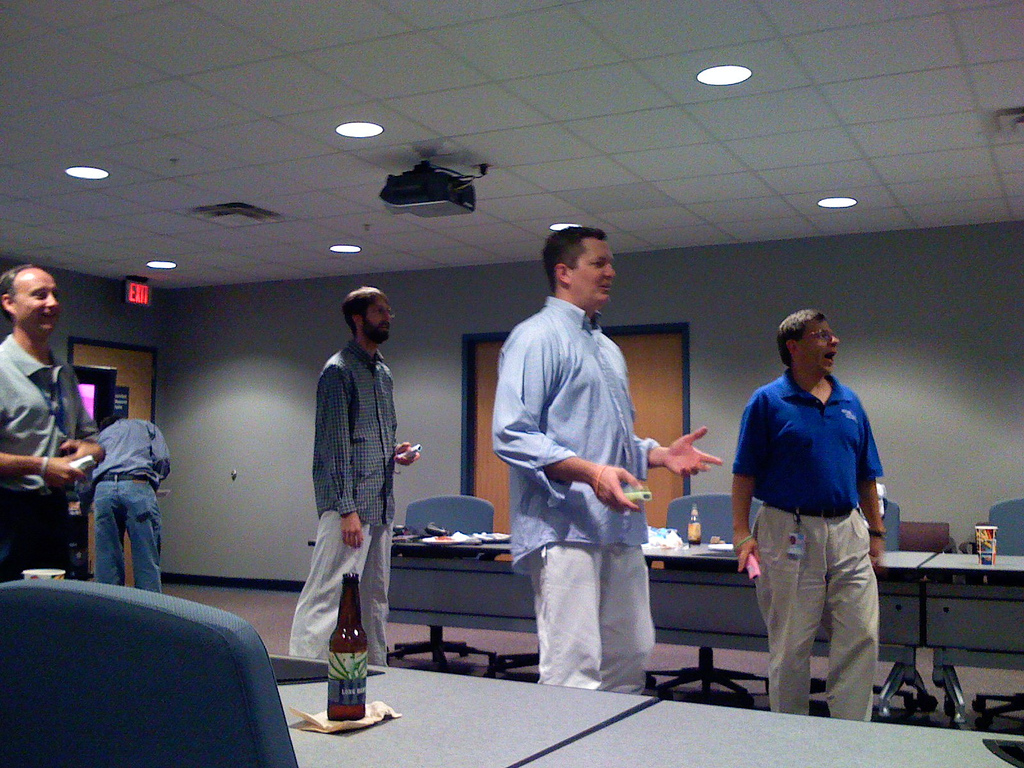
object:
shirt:
[733, 369, 886, 519]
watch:
[870, 528, 886, 537]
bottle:
[325, 572, 369, 721]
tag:
[788, 531, 805, 561]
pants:
[751, 508, 880, 721]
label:
[325, 651, 371, 707]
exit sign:
[128, 284, 150, 306]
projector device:
[380, 160, 479, 219]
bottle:
[329, 575, 365, 718]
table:
[265, 655, 1021, 766]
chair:
[0, 577, 299, 766]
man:
[74, 419, 170, 592]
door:
[68, 338, 158, 588]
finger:
[687, 425, 709, 442]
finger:
[696, 453, 723, 467]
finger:
[614, 468, 642, 490]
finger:
[611, 488, 639, 510]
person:
[287, 287, 426, 666]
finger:
[348, 529, 354, 548]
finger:
[677, 466, 686, 478]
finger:
[679, 464, 699, 476]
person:
[731, 308, 887, 720]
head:
[540, 227, 619, 309]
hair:
[544, 226, 609, 292]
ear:
[555, 263, 572, 284]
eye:
[588, 258, 615, 269]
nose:
[602, 263, 616, 278]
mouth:
[595, 281, 611, 292]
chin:
[573, 289, 612, 306]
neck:
[551, 289, 589, 317]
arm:
[488, 315, 597, 486]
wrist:
[555, 457, 598, 487]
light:
[696, 65, 754, 87]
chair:
[403, 494, 491, 531]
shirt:
[488, 297, 657, 578]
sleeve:
[731, 388, 770, 481]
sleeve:
[848, 389, 884, 484]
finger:
[737, 546, 751, 573]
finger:
[870, 551, 879, 570]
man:
[490, 224, 728, 695]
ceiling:
[0, 1, 1022, 292]